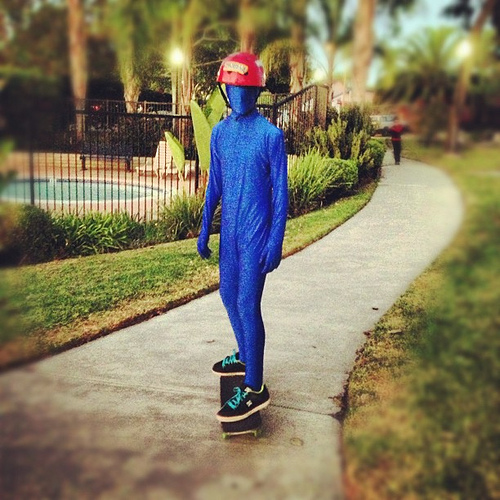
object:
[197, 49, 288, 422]
man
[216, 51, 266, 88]
helmet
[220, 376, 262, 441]
skateboard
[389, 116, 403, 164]
man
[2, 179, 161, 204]
pool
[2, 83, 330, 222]
fence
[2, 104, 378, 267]
bushes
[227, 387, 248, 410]
laces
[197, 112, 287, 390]
bodysuit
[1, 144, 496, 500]
ground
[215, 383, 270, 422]
foot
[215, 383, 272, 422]
shoes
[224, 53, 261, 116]
head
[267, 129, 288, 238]
arm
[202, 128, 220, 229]
arm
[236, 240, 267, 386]
leg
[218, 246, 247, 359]
leg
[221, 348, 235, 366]
laces